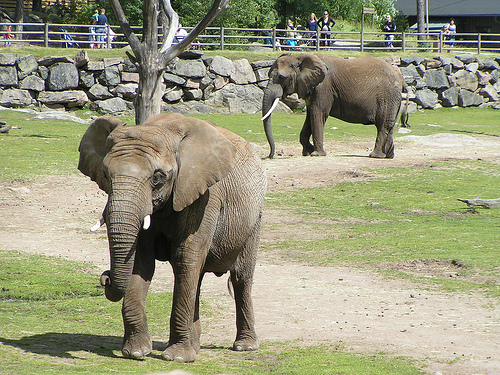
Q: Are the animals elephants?
A: Yes, all the animals are elephants.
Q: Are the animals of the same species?
A: Yes, all the animals are elephants.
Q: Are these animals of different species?
A: No, all the animals are elephants.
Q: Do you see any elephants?
A: Yes, there are elephants.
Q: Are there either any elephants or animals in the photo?
A: Yes, there are elephants.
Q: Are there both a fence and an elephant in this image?
A: Yes, there are both an elephant and a fence.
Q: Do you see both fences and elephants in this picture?
A: Yes, there are both elephants and a fence.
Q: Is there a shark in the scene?
A: No, there are no sharks.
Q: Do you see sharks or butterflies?
A: No, there are no sharks or butterflies.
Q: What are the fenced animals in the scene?
A: The animals are elephants.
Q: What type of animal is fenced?
A: The animal is elephants.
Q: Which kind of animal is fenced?
A: The animal is elephants.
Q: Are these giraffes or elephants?
A: These are elephants.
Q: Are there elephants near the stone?
A: Yes, there are elephants near the stone.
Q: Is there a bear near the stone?
A: No, there are elephants near the stone.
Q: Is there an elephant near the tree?
A: Yes, there are elephants near the tree.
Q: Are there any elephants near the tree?
A: Yes, there are elephants near the tree.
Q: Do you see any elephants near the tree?
A: Yes, there are elephants near the tree.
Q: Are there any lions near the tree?
A: No, there are elephants near the tree.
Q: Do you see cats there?
A: No, there are no cats.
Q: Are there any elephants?
A: Yes, there is an elephant.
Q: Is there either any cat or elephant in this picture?
A: Yes, there is an elephant.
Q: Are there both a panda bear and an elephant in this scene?
A: No, there is an elephant but no panda bears.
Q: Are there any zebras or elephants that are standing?
A: Yes, the elephant is standing.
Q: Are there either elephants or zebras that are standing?
A: Yes, the elephant is standing.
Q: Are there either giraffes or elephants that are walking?
A: Yes, the elephant is walking.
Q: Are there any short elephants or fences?
A: Yes, there is a short elephant.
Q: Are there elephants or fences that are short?
A: Yes, the elephant is short.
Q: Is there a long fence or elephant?
A: Yes, there is a long elephant.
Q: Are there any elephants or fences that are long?
A: Yes, the elephant is long.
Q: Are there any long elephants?
A: Yes, there is a long elephant.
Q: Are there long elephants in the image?
A: Yes, there is a long elephant.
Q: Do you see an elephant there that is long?
A: Yes, there is an elephant that is long.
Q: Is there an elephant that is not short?
A: Yes, there is a long elephant.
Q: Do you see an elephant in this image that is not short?
A: Yes, there is a long elephant.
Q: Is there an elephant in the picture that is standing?
A: Yes, there is an elephant that is standing.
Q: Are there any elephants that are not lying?
A: Yes, there is an elephant that is standing.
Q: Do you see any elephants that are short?
A: Yes, there is a short elephant.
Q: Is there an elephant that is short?
A: Yes, there is an elephant that is short.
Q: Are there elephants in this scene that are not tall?
A: Yes, there is a short elephant.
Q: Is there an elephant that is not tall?
A: Yes, there is a short elephant.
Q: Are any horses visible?
A: No, there are no horses.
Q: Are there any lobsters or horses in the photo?
A: No, there are no horses or lobsters.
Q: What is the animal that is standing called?
A: The animal is an elephant.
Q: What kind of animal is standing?
A: The animal is an elephant.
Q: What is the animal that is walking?
A: The animal is an elephant.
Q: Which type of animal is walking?
A: The animal is an elephant.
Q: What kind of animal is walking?
A: The animal is an elephant.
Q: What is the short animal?
A: The animal is an elephant.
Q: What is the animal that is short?
A: The animal is an elephant.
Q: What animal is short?
A: The animal is an elephant.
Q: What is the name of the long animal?
A: The animal is an elephant.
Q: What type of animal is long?
A: The animal is an elephant.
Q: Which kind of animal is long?
A: The animal is an elephant.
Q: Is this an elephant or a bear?
A: This is an elephant.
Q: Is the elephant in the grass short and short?
A: No, the elephant is short but long.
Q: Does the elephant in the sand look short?
A: Yes, the elephant is short.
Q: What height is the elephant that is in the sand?
A: The elephant is short.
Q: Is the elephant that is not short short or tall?
A: The elephant is short.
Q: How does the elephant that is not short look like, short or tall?
A: The elephant is short.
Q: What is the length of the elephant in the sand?
A: The elephant is long.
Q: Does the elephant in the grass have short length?
A: No, the elephant is long.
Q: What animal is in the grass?
A: The animal is an elephant.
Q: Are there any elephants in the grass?
A: Yes, there is an elephant in the grass.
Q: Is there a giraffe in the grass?
A: No, there is an elephant in the grass.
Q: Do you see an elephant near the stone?
A: Yes, there is an elephant near the stone.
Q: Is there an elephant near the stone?
A: Yes, there is an elephant near the stone.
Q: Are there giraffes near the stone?
A: No, there is an elephant near the stone.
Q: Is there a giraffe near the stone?
A: No, there is an elephant near the stone.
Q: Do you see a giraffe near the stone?
A: No, there is an elephant near the stone.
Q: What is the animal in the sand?
A: The animal is an elephant.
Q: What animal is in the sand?
A: The animal is an elephant.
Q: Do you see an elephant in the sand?
A: Yes, there is an elephant in the sand.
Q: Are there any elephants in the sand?
A: Yes, there is an elephant in the sand.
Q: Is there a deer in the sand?
A: No, there is an elephant in the sand.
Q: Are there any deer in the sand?
A: No, there is an elephant in the sand.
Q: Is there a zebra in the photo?
A: No, there are no zebras.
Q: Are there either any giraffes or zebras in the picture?
A: No, there are no zebras or giraffes.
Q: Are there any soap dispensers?
A: No, there are no soap dispensers.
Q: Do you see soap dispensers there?
A: No, there are no soap dispensers.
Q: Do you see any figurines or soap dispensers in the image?
A: No, there are no soap dispensers or figurines.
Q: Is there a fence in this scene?
A: Yes, there is a fence.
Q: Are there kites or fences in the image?
A: Yes, there is a fence.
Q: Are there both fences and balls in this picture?
A: No, there is a fence but no balls.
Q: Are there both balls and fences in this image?
A: No, there is a fence but no balls.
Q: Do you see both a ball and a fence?
A: No, there is a fence but no balls.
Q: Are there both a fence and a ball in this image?
A: No, there is a fence but no balls.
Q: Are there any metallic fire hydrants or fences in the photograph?
A: Yes, there is a metal fence.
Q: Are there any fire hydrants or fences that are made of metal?
A: Yes, the fence is made of metal.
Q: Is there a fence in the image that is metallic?
A: Yes, there is a metal fence.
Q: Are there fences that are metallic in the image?
A: Yes, there is a metal fence.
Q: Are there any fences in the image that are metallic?
A: Yes, there is a fence that is metallic.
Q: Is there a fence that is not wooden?
A: Yes, there is a metallic fence.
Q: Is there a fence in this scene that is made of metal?
A: Yes, there is a fence that is made of metal.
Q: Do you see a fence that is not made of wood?
A: Yes, there is a fence that is made of metal.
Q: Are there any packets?
A: No, there are no packets.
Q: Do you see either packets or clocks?
A: No, there are no packets or clocks.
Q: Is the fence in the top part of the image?
A: Yes, the fence is in the top of the image.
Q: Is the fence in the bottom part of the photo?
A: No, the fence is in the top of the image.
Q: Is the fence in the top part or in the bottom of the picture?
A: The fence is in the top of the image.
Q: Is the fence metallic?
A: Yes, the fence is metallic.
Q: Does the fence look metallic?
A: Yes, the fence is metallic.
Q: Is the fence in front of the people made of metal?
A: Yes, the fence is made of metal.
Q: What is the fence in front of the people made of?
A: The fence is made of metal.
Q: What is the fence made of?
A: The fence is made of metal.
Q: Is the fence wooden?
A: No, the fence is metallic.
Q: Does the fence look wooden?
A: No, the fence is metallic.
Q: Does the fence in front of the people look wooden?
A: No, the fence is metallic.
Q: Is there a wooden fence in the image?
A: No, there is a fence but it is metallic.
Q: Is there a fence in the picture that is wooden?
A: No, there is a fence but it is metallic.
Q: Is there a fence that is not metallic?
A: No, there is a fence but it is metallic.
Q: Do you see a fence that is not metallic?
A: No, there is a fence but it is metallic.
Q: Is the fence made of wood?
A: No, the fence is made of metal.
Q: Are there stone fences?
A: No, there is a fence but it is made of metal.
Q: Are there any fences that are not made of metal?
A: No, there is a fence but it is made of metal.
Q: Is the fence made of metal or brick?
A: The fence is made of metal.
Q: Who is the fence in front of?
A: The fence is in front of the people.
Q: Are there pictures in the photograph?
A: No, there are no pictures.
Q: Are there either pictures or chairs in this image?
A: No, there are no pictures or chairs.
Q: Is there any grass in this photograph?
A: Yes, there is grass.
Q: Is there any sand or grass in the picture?
A: Yes, there is grass.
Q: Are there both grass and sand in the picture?
A: Yes, there are both grass and sand.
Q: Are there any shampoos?
A: No, there are no shampoos.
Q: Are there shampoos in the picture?
A: No, there are no shampoos.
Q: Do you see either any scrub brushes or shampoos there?
A: No, there are no shampoos or scrub brushes.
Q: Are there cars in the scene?
A: No, there are no cars.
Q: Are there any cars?
A: No, there are no cars.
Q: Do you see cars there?
A: No, there are no cars.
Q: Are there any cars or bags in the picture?
A: No, there are no cars or bags.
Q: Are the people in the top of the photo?
A: Yes, the people are in the top of the image.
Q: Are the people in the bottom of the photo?
A: No, the people are in the top of the image.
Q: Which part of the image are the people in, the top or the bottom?
A: The people are in the top of the image.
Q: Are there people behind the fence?
A: Yes, there are people behind the fence.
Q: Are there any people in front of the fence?
A: No, the people are behind the fence.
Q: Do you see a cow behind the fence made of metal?
A: No, there are people behind the fence.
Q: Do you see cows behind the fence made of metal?
A: No, there are people behind the fence.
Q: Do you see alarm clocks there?
A: No, there are no alarm clocks.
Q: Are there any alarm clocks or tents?
A: No, there are no alarm clocks or tents.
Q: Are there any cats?
A: No, there are no cats.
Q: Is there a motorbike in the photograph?
A: No, there are no motorcycles.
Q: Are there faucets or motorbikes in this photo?
A: No, there are no motorbikes or faucets.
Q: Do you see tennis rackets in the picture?
A: No, there are no tennis rackets.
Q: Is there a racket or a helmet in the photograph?
A: No, there are no rackets or helmets.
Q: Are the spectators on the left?
A: Yes, the spectators are on the left of the image.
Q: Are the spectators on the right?
A: No, the spectators are on the left of the image.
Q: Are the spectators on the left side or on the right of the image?
A: The spectators are on the left of the image.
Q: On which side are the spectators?
A: The spectators are on the left of the image.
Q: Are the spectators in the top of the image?
A: Yes, the spectators are in the top of the image.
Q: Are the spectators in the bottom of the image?
A: No, the spectators are in the top of the image.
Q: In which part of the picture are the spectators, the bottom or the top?
A: The spectators are in the top of the image.